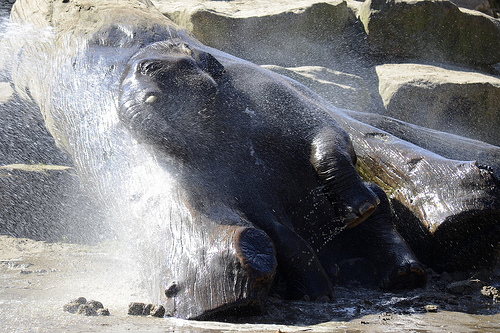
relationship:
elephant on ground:
[118, 39, 426, 302] [0, 229, 498, 333]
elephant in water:
[118, 39, 426, 302] [0, 16, 497, 333]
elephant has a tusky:
[118, 39, 426, 302] [145, 94, 156, 101]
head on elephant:
[119, 42, 218, 148] [118, 39, 426, 302]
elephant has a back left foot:
[118, 39, 426, 302] [380, 257, 428, 289]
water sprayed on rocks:
[0, 16, 497, 333] [0, 1, 498, 238]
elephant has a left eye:
[118, 39, 426, 302] [147, 60, 159, 70]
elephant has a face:
[118, 39, 426, 302] [120, 61, 176, 116]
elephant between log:
[118, 39, 426, 302] [6, 0, 499, 320]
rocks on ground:
[62, 269, 498, 316] [0, 229, 498, 333]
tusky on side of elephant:
[145, 94, 156, 101] [118, 39, 426, 302]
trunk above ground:
[126, 100, 192, 160] [0, 229, 498, 333]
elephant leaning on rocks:
[118, 39, 426, 302] [0, 1, 498, 238]